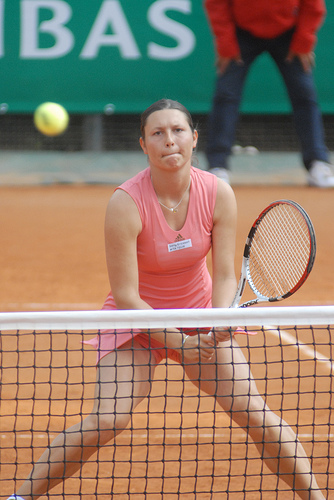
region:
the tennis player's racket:
[233, 190, 320, 304]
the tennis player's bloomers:
[146, 348, 187, 369]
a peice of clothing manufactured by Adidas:
[162, 227, 192, 251]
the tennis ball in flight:
[29, 84, 70, 141]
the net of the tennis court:
[0, 329, 308, 498]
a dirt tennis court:
[10, 240, 78, 294]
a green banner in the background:
[12, 70, 196, 91]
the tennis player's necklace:
[142, 182, 197, 220]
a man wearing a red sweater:
[211, 0, 326, 188]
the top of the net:
[0, 311, 331, 320]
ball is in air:
[23, 97, 111, 183]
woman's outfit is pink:
[71, 144, 265, 338]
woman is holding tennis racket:
[76, 74, 327, 317]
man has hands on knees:
[193, 0, 316, 196]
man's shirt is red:
[194, 0, 310, 85]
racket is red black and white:
[213, 172, 331, 318]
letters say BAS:
[16, 3, 210, 87]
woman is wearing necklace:
[134, 169, 204, 218]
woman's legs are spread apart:
[20, 334, 324, 496]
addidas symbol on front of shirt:
[163, 229, 197, 248]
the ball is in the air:
[3, 78, 108, 143]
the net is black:
[18, 327, 322, 477]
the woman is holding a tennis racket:
[87, 73, 314, 295]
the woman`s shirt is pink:
[103, 89, 218, 255]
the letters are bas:
[20, 0, 199, 61]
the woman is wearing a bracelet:
[168, 323, 194, 352]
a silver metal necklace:
[135, 169, 216, 219]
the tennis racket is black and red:
[224, 195, 333, 300]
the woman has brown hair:
[102, 79, 214, 175]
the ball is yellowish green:
[6, 84, 96, 150]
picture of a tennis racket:
[275, 200, 327, 325]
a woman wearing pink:
[130, 99, 288, 352]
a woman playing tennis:
[108, 95, 282, 253]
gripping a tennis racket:
[183, 274, 235, 380]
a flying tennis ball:
[26, 97, 89, 146]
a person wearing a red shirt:
[208, 7, 330, 166]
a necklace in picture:
[170, 198, 189, 233]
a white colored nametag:
[158, 232, 213, 258]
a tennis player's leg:
[213, 370, 304, 494]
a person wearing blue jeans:
[230, 54, 327, 189]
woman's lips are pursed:
[130, 99, 211, 177]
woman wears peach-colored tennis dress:
[81, 92, 275, 368]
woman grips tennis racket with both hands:
[181, 196, 319, 357]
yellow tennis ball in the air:
[32, 96, 73, 138]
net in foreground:
[2, 303, 332, 498]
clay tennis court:
[0, 177, 332, 499]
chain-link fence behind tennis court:
[2, 0, 331, 183]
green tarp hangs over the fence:
[0, 0, 332, 182]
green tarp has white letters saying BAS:
[1, 1, 333, 178]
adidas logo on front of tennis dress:
[168, 228, 193, 246]